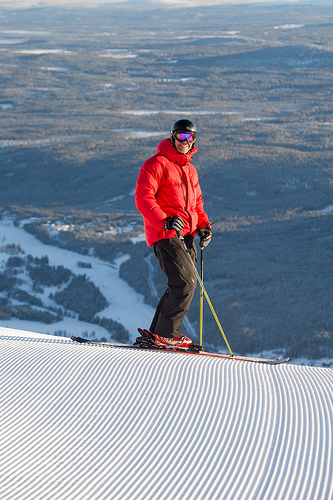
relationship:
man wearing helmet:
[131, 115, 213, 350] [169, 117, 197, 144]